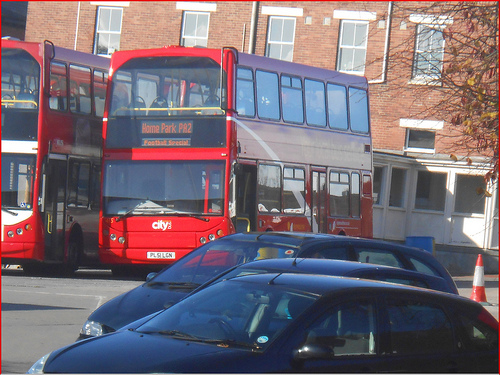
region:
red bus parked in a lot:
[92, 40, 428, 222]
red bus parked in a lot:
[23, 33, 73, 269]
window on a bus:
[227, 62, 283, 118]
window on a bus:
[276, 65, 326, 135]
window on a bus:
[330, 75, 371, 145]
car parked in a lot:
[160, 270, 490, 370]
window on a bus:
[111, 56, 218, 111]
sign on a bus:
[135, 118, 206, 151]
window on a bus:
[90, 153, 231, 216]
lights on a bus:
[97, 224, 129, 253]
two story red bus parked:
[106, 52, 223, 248]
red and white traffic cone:
[470, 253, 488, 308]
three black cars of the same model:
[29, 232, 483, 374]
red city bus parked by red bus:
[8, 53, 236, 262]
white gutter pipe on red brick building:
[374, 39, 396, 83]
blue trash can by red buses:
[407, 234, 435, 251]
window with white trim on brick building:
[411, 17, 448, 87]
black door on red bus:
[45, 155, 69, 261]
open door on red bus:
[231, 166, 256, 235]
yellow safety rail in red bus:
[238, 215, 250, 230]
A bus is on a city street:
[20, 16, 483, 346]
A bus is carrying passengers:
[25, 12, 466, 370]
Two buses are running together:
[0, 2, 475, 337]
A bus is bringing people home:
[5, 17, 497, 347]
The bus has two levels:
[6, 12, 466, 342]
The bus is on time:
[8, 20, 490, 321]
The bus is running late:
[30, 10, 450, 366]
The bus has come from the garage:
[25, 30, 480, 350]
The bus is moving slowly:
[1, 20, 496, 338]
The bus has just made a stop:
[7, 20, 490, 374]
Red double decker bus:
[86, 46, 331, 246]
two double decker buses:
[19, 41, 314, 257]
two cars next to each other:
[137, 204, 335, 358]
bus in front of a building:
[128, 31, 466, 227]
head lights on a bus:
[97, 225, 251, 264]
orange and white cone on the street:
[453, 238, 498, 308]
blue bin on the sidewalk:
[388, 204, 452, 266]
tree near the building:
[398, 24, 476, 153]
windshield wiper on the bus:
[106, 190, 243, 239]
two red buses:
[18, 43, 228, 167]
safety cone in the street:
[459, 239, 499, 315]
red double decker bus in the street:
[102, 42, 389, 269]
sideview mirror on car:
[295, 334, 332, 363]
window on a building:
[400, 123, 442, 157]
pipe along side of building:
[369, 7, 406, 86]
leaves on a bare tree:
[379, 3, 498, 160]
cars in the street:
[21, 224, 498, 373]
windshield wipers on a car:
[141, 324, 258, 359]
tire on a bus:
[59, 221, 90, 277]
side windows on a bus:
[239, 65, 368, 139]